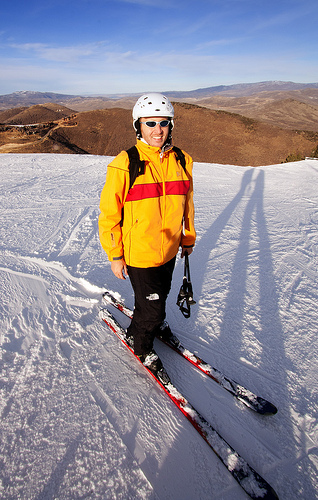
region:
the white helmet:
[131, 93, 173, 142]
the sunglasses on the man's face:
[137, 120, 171, 128]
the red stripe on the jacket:
[125, 179, 189, 201]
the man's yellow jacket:
[97, 138, 196, 267]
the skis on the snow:
[99, 290, 278, 498]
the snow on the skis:
[98, 291, 277, 499]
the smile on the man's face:
[151, 135, 161, 140]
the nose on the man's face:
[153, 124, 162, 133]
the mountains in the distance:
[0, 81, 317, 167]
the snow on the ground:
[0, 153, 316, 499]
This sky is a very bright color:
[271, 13, 295, 60]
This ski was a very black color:
[187, 422, 234, 449]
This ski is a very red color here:
[168, 392, 197, 421]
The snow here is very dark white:
[70, 373, 176, 424]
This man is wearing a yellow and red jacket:
[140, 151, 184, 239]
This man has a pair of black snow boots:
[140, 337, 175, 383]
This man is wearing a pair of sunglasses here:
[149, 113, 182, 141]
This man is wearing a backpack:
[125, 153, 149, 203]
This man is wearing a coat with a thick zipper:
[157, 149, 167, 166]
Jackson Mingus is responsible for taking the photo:
[97, 150, 282, 491]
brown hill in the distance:
[16, 103, 51, 122]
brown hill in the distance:
[9, 92, 53, 103]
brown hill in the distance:
[75, 92, 116, 105]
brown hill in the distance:
[82, 107, 133, 145]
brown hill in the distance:
[169, 100, 279, 157]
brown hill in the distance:
[238, 91, 312, 122]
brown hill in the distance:
[204, 73, 309, 98]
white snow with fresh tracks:
[5, 278, 113, 498]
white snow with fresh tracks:
[4, 156, 91, 285]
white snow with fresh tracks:
[212, 229, 301, 383]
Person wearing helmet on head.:
[128, 96, 197, 129]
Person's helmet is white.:
[131, 78, 171, 132]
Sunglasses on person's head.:
[140, 116, 184, 138]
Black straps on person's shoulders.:
[104, 144, 208, 183]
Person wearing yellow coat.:
[107, 154, 233, 248]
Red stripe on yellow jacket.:
[121, 177, 212, 202]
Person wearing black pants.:
[130, 280, 170, 322]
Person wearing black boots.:
[125, 311, 182, 383]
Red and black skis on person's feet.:
[151, 374, 257, 435]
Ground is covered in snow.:
[46, 387, 129, 445]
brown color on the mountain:
[205, 112, 257, 137]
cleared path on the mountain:
[51, 117, 79, 132]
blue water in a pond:
[10, 114, 48, 136]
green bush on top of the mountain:
[290, 125, 317, 139]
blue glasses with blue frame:
[138, 116, 190, 129]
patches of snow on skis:
[168, 385, 224, 454]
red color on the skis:
[159, 387, 177, 412]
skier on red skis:
[101, 92, 204, 371]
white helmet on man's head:
[114, 88, 194, 132]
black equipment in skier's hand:
[178, 246, 198, 312]